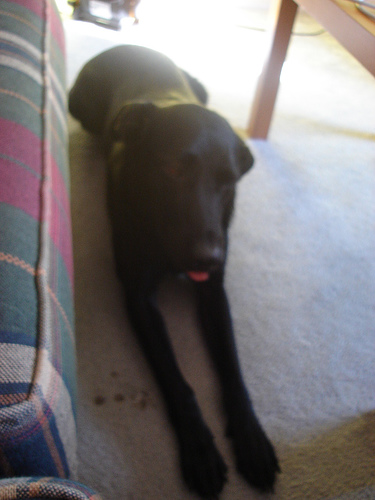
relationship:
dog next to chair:
[64, 21, 303, 495] [3, 0, 80, 500]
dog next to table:
[64, 21, 303, 495] [238, 0, 373, 207]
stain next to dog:
[91, 371, 150, 410] [64, 45, 281, 494]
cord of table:
[212, 7, 302, 136] [242, 1, 373, 144]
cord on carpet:
[212, 7, 302, 136] [208, 46, 373, 499]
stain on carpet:
[91, 371, 150, 410] [74, 0, 373, 499]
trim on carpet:
[271, 406, 360, 494] [259, 352, 353, 480]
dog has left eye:
[64, 45, 281, 494] [161, 159, 177, 172]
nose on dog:
[186, 237, 229, 267] [90, 104, 310, 474]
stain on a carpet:
[91, 392, 106, 405] [74, 0, 373, 499]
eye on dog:
[212, 170, 240, 197] [64, 45, 281, 494]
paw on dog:
[224, 422, 291, 493] [64, 45, 281, 494]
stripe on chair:
[2, 343, 77, 478] [3, 0, 80, 500]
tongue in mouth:
[188, 270, 209, 281] [170, 234, 221, 291]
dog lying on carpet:
[64, 45, 281, 494] [282, 309, 350, 412]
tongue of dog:
[190, 270, 210, 281] [64, 45, 281, 494]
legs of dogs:
[138, 289, 286, 490] [64, 41, 295, 485]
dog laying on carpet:
[64, 21, 303, 495] [303, 295, 340, 416]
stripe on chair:
[9, 132, 57, 210] [3, 62, 77, 213]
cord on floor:
[212, 22, 311, 135] [162, 14, 348, 318]